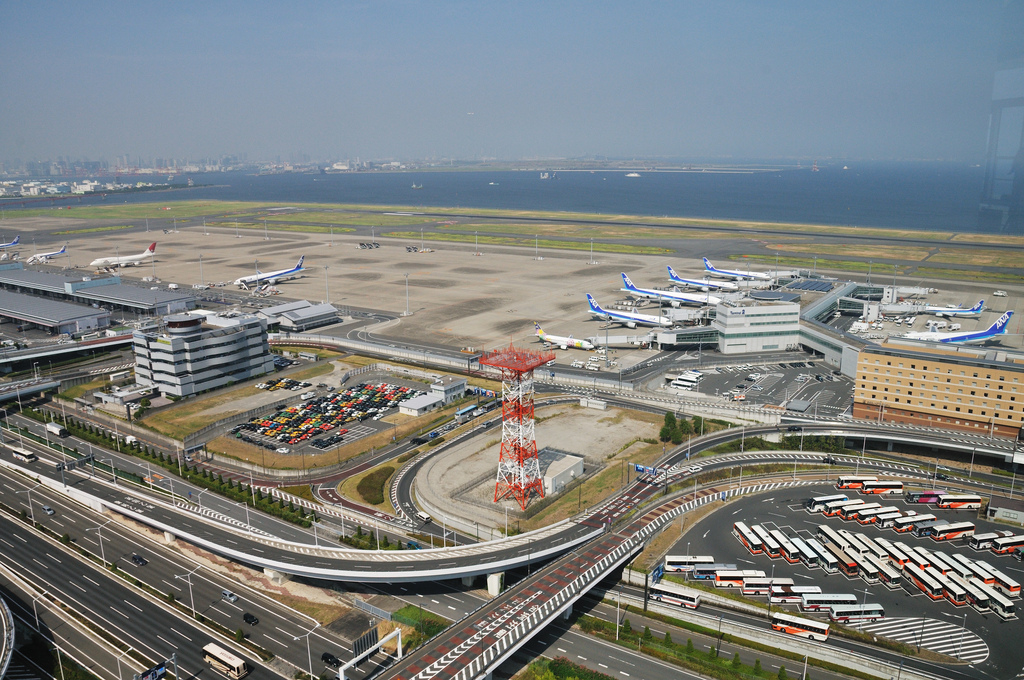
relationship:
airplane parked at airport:
[584, 292, 675, 329] [5, 199, 991, 671]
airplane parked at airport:
[617, 271, 719, 308] [5, 199, 991, 671]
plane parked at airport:
[698, 253, 776, 288] [5, 199, 991, 671]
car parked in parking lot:
[335, 422, 351, 436] [229, 366, 430, 457]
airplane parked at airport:
[81, 242, 161, 273] [5, 199, 991, 671]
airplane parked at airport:
[230, 251, 311, 290] [5, 199, 991, 671]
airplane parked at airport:
[579, 288, 681, 334] [5, 199, 991, 671]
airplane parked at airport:
[612, 269, 721, 311] [5, 199, 991, 671]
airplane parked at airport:
[657, 260, 744, 291] [5, 199, 991, 671]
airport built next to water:
[5, 199, 991, 671] [31, 163, 993, 237]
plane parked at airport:
[891, 307, 993, 346] [5, 199, 991, 671]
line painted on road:
[154, 631, 181, 649] [1, 515, 287, 676]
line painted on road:
[169, 623, 193, 641] [1, 515, 287, 676]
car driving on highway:
[236, 606, 262, 628] [3, 471, 388, 677]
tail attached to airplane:
[145, 238, 159, 252] [83, 236, 163, 269]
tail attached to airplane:
[580, 290, 602, 316] [579, 290, 679, 332]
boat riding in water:
[621, 169, 643, 178] [3, 160, 993, 234]